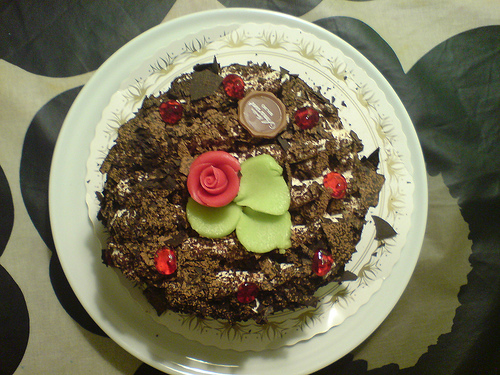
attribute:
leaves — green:
[187, 150, 296, 250]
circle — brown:
[238, 84, 289, 141]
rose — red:
[180, 152, 242, 211]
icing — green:
[238, 153, 292, 253]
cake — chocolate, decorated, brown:
[96, 61, 383, 324]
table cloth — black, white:
[2, 5, 62, 372]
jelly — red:
[156, 248, 173, 272]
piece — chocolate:
[375, 221, 396, 237]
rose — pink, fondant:
[187, 146, 238, 209]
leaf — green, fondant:
[235, 146, 295, 216]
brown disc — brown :
[231, 89, 291, 137]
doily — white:
[82, 20, 419, 348]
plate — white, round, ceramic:
[46, 9, 427, 369]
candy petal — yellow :
[227, 154, 294, 223]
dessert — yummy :
[92, 61, 384, 320]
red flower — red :
[320, 171, 351, 198]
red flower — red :
[311, 246, 339, 272]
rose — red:
[184, 147, 243, 209]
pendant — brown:
[237, 88, 289, 141]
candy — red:
[158, 96, 185, 124]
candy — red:
[222, 73, 250, 100]